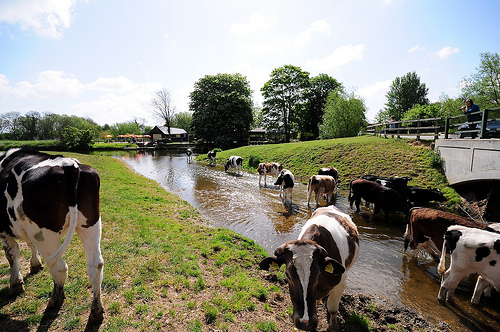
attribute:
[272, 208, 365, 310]
cow — brown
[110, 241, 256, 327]
grass — dead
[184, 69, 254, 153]
leaves — green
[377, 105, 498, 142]
railing — wooden